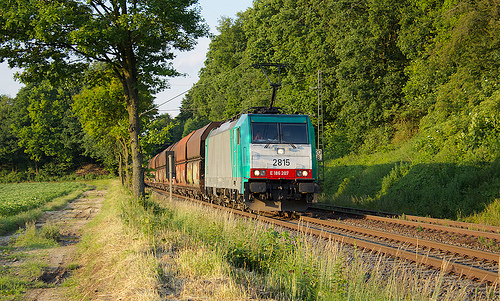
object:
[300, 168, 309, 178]
headlight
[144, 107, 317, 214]
train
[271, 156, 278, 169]
number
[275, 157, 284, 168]
number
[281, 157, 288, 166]
number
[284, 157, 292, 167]
number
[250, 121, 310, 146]
windshield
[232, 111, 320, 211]
engine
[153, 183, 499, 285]
tracks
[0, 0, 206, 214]
tree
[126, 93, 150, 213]
trunk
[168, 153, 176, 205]
pole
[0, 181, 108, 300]
road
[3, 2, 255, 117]
sky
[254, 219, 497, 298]
gravel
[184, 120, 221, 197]
car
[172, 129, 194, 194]
car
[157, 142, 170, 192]
car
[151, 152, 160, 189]
car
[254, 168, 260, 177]
headlight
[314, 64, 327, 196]
pole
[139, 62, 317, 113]
wires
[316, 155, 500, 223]
shadow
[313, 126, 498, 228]
grass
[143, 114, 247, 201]
side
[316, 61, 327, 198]
ladder tower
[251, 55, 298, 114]
contraption